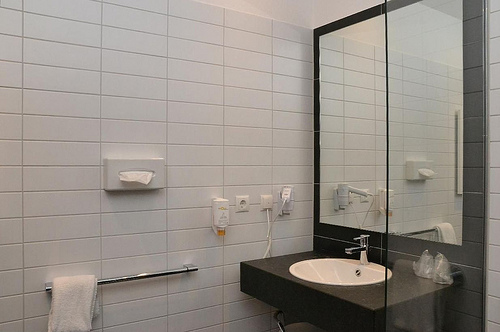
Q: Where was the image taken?
A: It was taken at the bathroom.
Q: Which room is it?
A: It is a bathroom.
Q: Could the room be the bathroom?
A: Yes, it is the bathroom.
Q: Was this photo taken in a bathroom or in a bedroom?
A: It was taken at a bathroom.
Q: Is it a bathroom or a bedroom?
A: It is a bathroom.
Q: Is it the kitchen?
A: No, it is the bathroom.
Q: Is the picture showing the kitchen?
A: No, the picture is showing the bathroom.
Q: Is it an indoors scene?
A: Yes, it is indoors.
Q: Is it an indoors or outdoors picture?
A: It is indoors.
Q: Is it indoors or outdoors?
A: It is indoors.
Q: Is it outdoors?
A: No, it is indoors.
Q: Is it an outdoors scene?
A: No, it is indoors.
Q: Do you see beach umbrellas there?
A: No, there are no beach umbrellas.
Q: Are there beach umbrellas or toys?
A: No, there are no beach umbrellas or toys.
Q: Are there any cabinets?
A: No, there are no cabinets.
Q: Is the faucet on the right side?
A: Yes, the faucet is on the right of the image.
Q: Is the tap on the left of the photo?
A: No, the tap is on the right of the image.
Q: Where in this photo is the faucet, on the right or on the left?
A: The faucet is on the right of the image.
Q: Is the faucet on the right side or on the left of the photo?
A: The faucet is on the right of the image.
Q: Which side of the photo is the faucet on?
A: The faucet is on the right of the image.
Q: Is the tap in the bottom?
A: Yes, the tap is in the bottom of the image.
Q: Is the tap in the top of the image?
A: No, the tap is in the bottom of the image.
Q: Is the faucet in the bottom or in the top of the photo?
A: The faucet is in the bottom of the image.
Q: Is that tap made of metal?
A: Yes, the tap is made of metal.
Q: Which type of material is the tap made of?
A: The tap is made of metal.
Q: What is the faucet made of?
A: The tap is made of metal.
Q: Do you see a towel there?
A: Yes, there is a towel.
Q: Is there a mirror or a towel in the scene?
A: Yes, there is a towel.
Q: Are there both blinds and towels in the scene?
A: No, there is a towel but no blinds.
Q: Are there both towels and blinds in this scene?
A: No, there is a towel but no blinds.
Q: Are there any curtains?
A: No, there are no curtains.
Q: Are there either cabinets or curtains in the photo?
A: No, there are no curtains or cabinets.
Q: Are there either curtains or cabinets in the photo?
A: No, there are no curtains or cabinets.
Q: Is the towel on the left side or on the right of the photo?
A: The towel is on the left of the image.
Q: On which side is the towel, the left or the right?
A: The towel is on the left of the image.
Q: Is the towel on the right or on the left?
A: The towel is on the left of the image.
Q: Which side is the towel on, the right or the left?
A: The towel is on the left of the image.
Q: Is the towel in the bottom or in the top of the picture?
A: The towel is in the bottom of the image.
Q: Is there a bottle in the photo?
A: No, there are no bottles.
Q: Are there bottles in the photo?
A: No, there are no bottles.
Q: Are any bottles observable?
A: No, there are no bottles.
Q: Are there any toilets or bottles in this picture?
A: No, there are no bottles or toilets.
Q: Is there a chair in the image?
A: No, there are no chairs.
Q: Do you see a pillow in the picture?
A: No, there are no pillows.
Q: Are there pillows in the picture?
A: No, there are no pillows.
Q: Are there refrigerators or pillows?
A: No, there are no pillows or refrigerators.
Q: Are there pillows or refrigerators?
A: No, there are no pillows or refrigerators.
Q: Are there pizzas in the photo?
A: No, there are no pizzas.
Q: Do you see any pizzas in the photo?
A: No, there are no pizzas.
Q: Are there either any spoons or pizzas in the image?
A: No, there are no pizzas or spoons.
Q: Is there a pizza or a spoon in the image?
A: No, there are no pizzas or spoons.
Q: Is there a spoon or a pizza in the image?
A: No, there are no pizzas or spoons.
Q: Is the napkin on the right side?
A: No, the napkin is on the left of the image.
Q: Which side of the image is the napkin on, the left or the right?
A: The napkin is on the left of the image.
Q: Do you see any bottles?
A: No, there are no bottles.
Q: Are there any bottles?
A: No, there are no bottles.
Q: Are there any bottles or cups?
A: No, there are no bottles or cups.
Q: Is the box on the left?
A: Yes, the box is on the left of the image.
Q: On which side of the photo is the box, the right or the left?
A: The box is on the left of the image.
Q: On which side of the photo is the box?
A: The box is on the left of the image.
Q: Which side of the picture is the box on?
A: The box is on the left of the image.